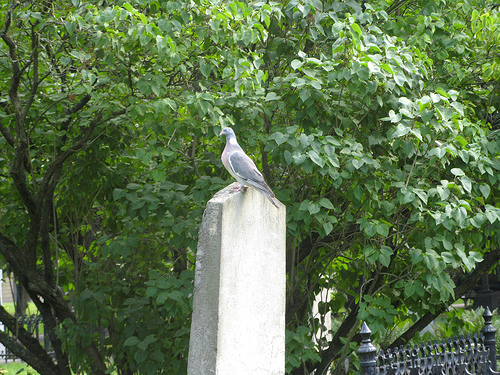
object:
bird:
[218, 127, 276, 199]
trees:
[0, 0, 282, 375]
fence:
[355, 304, 500, 373]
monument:
[183, 181, 289, 375]